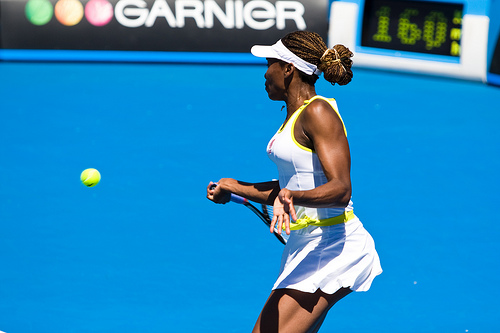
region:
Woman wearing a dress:
[260, 92, 390, 297]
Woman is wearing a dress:
[262, 92, 392, 304]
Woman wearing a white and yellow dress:
[260, 93, 390, 298]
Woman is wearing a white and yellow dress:
[262, 91, 387, 298]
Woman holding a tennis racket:
[205, 172, 297, 246]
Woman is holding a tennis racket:
[209, 177, 297, 247]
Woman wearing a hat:
[247, 34, 324, 76]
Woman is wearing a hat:
[245, 37, 327, 76]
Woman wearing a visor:
[247, 35, 325, 78]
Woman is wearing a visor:
[250, 36, 325, 78]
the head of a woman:
[253, 30, 376, 111]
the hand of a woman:
[253, 185, 333, 248]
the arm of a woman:
[258, 90, 378, 235]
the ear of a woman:
[270, 58, 308, 89]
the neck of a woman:
[276, 69, 329, 117]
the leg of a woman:
[260, 257, 428, 322]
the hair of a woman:
[239, 19, 381, 114]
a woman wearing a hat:
[226, 18, 421, 262]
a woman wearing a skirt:
[245, 167, 452, 305]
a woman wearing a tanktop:
[226, 28, 431, 242]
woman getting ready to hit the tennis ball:
[206, 33, 383, 331]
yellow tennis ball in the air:
[79, 166, 101, 186]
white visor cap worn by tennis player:
[250, 40, 323, 79]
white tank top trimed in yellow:
[266, 94, 357, 231]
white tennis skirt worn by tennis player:
[273, 218, 383, 292]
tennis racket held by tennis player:
[208, 180, 289, 245]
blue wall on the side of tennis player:
[0, 60, 499, 330]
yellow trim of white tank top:
[278, 208, 353, 228]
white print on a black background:
[113, 0, 308, 30]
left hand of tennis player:
[271, 187, 300, 232]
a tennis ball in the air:
[81, 167, 100, 186]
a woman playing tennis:
[211, 32, 381, 325]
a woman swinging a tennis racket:
[205, 29, 382, 331]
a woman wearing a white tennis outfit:
[211, 28, 380, 330]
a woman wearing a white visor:
[247, 28, 362, 105]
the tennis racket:
[213, 173, 291, 243]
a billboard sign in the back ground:
[7, 0, 329, 54]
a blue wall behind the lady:
[13, 73, 246, 155]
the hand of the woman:
[269, 185, 299, 235]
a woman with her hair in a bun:
[253, 35, 352, 100]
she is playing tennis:
[198, 36, 375, 311]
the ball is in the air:
[62, 140, 124, 201]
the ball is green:
[73, 147, 111, 192]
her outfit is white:
[206, 75, 383, 328]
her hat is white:
[234, 28, 313, 79]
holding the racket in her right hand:
[172, 165, 234, 232]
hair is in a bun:
[302, 40, 352, 75]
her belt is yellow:
[269, 206, 357, 244]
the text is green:
[354, 0, 463, 67]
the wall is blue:
[40, 85, 472, 290]